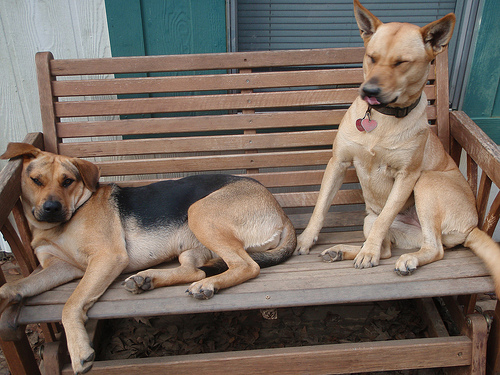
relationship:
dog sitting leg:
[292, 0, 497, 299] [348, 177, 401, 270]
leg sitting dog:
[352, 167, 419, 269] [317, 12, 484, 266]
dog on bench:
[295, 0, 498, 300] [3, 43, 498, 372]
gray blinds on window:
[233, 1, 461, 51] [229, 1, 496, 151]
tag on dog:
[356, 117, 378, 132] [295, 0, 498, 300]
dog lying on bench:
[3, 118, 300, 370] [28, 35, 494, 302]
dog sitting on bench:
[292, 0, 497, 299] [11, 54, 498, 294]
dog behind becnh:
[292, 0, 497, 299] [25, 43, 475, 293]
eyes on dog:
[359, 51, 413, 69] [295, 0, 498, 300]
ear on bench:
[2, 143, 40, 163] [3, 43, 498, 372]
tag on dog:
[362, 115, 375, 131] [295, 0, 498, 300]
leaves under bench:
[128, 322, 343, 348] [3, 43, 498, 372]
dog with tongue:
[295, 0, 498, 300] [366, 97, 379, 107]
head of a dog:
[1, 138, 98, 230] [3, 118, 300, 370]